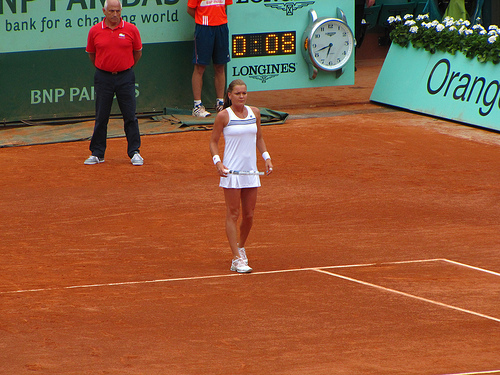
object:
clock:
[231, 30, 297, 59]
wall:
[226, 0, 355, 93]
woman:
[210, 79, 273, 273]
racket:
[223, 169, 265, 176]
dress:
[218, 104, 263, 189]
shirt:
[85, 16, 143, 74]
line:
[310, 257, 445, 270]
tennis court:
[0, 107, 498, 374]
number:
[280, 33, 295, 53]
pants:
[89, 68, 141, 156]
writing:
[232, 62, 296, 76]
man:
[82, 0, 143, 166]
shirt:
[187, 0, 233, 26]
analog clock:
[301, 8, 357, 80]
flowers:
[387, 14, 499, 65]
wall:
[368, 40, 499, 134]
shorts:
[193, 22, 230, 64]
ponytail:
[223, 80, 233, 109]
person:
[186, 0, 231, 118]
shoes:
[230, 246, 253, 274]